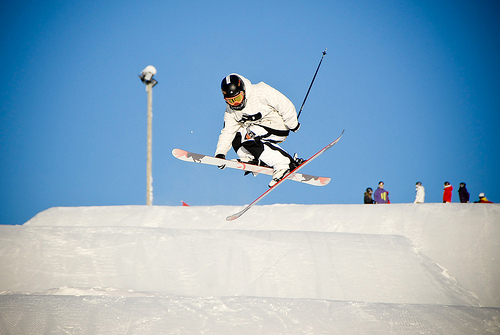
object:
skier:
[213, 70, 308, 189]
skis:
[171, 147, 331, 187]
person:
[212, 71, 303, 188]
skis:
[224, 128, 349, 222]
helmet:
[220, 73, 249, 111]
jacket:
[208, 82, 300, 155]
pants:
[229, 120, 297, 173]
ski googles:
[225, 91, 244, 105]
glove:
[213, 156, 230, 172]